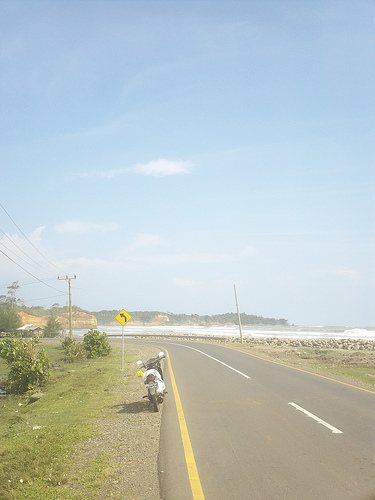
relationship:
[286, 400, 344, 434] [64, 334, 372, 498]
line in middle of road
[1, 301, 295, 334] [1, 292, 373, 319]
low hills along horizon line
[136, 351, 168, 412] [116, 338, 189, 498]
motorbike parked on shoulder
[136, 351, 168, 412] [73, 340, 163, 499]
motorbike parked in gravel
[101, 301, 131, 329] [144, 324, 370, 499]
road sign warning of curve in road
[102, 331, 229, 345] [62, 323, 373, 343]
guard rail at waters edge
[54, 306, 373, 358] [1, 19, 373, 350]
lake in background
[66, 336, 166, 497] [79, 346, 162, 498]
shoulder built next to shouler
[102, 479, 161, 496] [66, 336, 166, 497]
dirt covering shoulder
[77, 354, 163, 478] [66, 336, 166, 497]
gravel covering shoulder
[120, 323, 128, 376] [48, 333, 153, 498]
pole sitting in ground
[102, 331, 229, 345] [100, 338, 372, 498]
guard rail standing next to road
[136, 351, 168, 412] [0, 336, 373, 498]
motorbike parked next to highway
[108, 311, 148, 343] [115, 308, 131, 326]
arrow painted on road sign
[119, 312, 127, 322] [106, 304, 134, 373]
arrow painted on sign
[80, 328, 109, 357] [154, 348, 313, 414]
bush by road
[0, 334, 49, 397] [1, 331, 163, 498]
bush growing in dirt